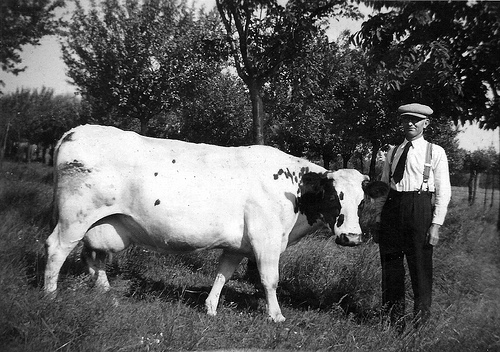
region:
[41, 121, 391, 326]
Black and white cow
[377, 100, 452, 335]
Man wearing suspenders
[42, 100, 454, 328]
Man standing by cow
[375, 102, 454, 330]
Man in white shirt and black pants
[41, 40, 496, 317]
Trees with foliage behind cow and man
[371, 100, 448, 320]
Man wearing black tie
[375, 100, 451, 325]
Man wearing cap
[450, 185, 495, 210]
Fencing and posts in pasture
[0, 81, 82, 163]
Trees in the distance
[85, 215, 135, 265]
Udders on cow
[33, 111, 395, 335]
a white cow on a field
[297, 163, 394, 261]
head of cow is pepper and salt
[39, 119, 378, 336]
body of cow is white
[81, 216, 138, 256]
udder of cow is full of milk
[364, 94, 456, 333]
old man stands next to a white cow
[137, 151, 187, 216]
three spots on the body of cow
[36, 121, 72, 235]
long tail of cow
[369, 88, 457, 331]
man wears a black tie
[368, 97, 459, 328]
man wears pants with suspenders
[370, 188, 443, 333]
pants of man are black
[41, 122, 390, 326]
cow with full udders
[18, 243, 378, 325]
shadow of cow on the grass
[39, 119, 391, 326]
black and white cow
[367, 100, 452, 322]
man in black pants and white shirt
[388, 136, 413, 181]
dark tie on man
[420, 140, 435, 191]
man's left suspender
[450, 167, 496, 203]
fence on man's left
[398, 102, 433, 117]
man's cap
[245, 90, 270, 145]
tree trunk closest to cow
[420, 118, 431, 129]
man's left ear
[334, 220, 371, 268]
nose of the cow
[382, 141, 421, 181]
black tie of man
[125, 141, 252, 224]
white fur of cow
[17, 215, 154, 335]
legs of a cow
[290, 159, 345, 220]
black fur of cow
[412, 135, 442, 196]
overalls on a guy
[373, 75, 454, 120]
hat of a guy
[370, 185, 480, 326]
pants attached to overalls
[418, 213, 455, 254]
left hand of guy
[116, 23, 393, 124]
trees in the background of photo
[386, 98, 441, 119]
Man wearing beige hat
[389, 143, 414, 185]
Man wears black tie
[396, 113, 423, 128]
Black glasses on man's face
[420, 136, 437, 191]
Man wearing brown suspenders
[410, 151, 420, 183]
Man wearing white shirt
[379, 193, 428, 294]
Man wearing black pants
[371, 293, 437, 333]
Grass covering man's feet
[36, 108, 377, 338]
Big black and white cow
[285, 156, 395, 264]
Cow's head is black and white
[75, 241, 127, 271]
Cow's nipples are full of milk